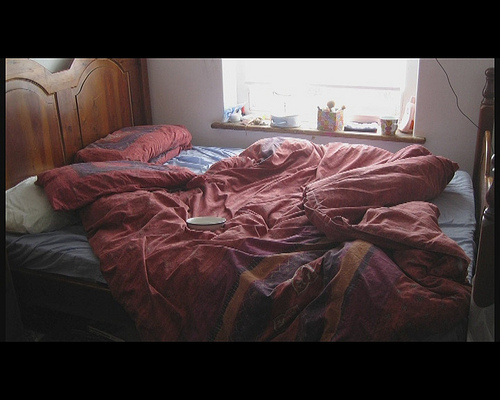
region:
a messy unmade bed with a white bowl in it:
[26, 89, 477, 301]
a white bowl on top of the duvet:
[184, 216, 230, 230]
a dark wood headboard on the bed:
[10, 61, 152, 186]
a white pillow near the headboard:
[10, 175, 77, 243]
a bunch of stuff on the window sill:
[227, 97, 419, 142]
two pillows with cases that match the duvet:
[38, 128, 198, 198]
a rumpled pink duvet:
[111, 156, 433, 313]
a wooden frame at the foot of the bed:
[459, 70, 499, 320]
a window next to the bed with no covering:
[216, 58, 423, 146]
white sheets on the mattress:
[19, 235, 100, 282]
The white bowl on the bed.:
[183, 209, 235, 235]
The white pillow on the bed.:
[1, 173, 78, 241]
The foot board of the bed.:
[471, 58, 499, 345]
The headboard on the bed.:
[5, 58, 152, 183]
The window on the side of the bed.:
[222, 59, 414, 122]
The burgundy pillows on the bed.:
[68, 118, 204, 166]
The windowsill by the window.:
[212, 120, 428, 144]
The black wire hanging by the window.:
[431, 58, 483, 150]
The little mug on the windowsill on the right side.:
[380, 116, 400, 136]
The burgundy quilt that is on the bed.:
[36, 107, 468, 342]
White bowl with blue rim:
[178, 205, 233, 237]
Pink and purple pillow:
[58, 98, 199, 177]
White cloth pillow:
[0, 155, 80, 252]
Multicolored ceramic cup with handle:
[369, 110, 404, 137]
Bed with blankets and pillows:
[0, 53, 492, 382]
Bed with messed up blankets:
[0, 58, 496, 390]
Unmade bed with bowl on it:
[2, 52, 497, 399]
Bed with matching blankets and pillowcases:
[2, 54, 489, 366]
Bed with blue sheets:
[0, 67, 483, 374]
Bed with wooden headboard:
[2, 58, 492, 390]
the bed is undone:
[10, 130, 471, 334]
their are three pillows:
[6, 123, 191, 233]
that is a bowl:
[185, 210, 227, 230]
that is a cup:
[374, 113, 406, 138]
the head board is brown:
[1, 54, 157, 122]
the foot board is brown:
[475, 64, 499, 309]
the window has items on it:
[221, 54, 420, 141]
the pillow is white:
[6, 171, 48, 235]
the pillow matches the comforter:
[79, 123, 196, 163]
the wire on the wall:
[435, 54, 474, 125]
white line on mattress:
[44, 263, 105, 294]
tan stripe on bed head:
[28, 98, 71, 166]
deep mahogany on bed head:
[26, 93, 39, 113]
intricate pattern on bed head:
[23, 81, 114, 156]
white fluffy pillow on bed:
[11, 191, 63, 232]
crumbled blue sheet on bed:
[28, 237, 94, 273]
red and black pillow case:
[121, 129, 193, 159]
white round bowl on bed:
[178, 205, 235, 237]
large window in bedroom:
[213, 73, 450, 143]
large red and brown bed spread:
[79, 140, 443, 323]